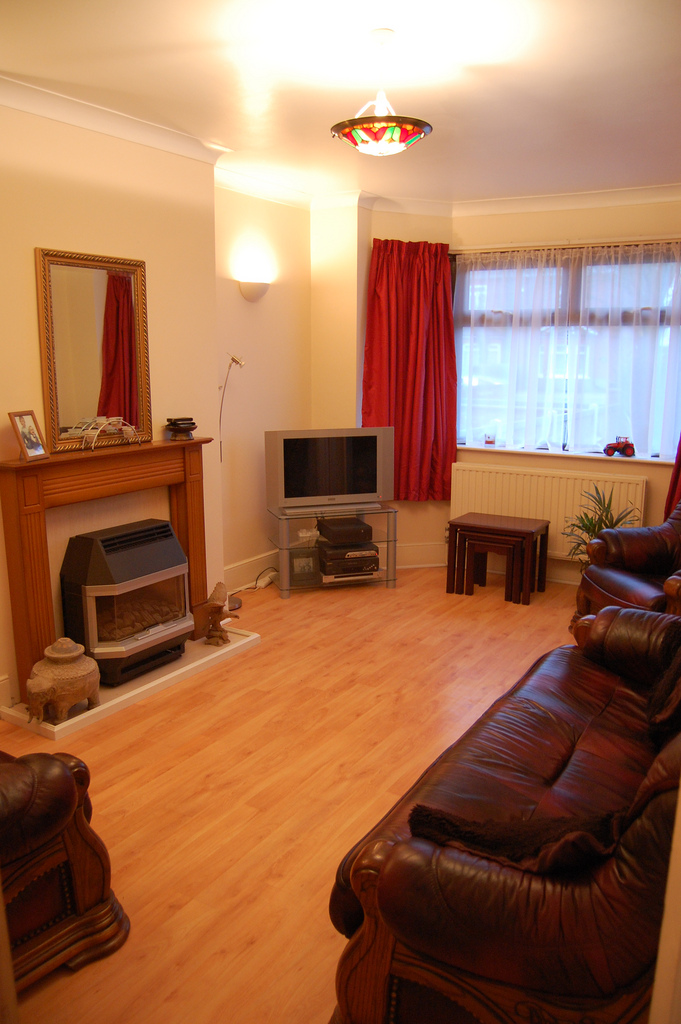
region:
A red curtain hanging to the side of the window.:
[369, 230, 452, 502]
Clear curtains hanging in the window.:
[458, 255, 676, 462]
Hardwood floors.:
[10, 556, 592, 1021]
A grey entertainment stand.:
[263, 508, 402, 596]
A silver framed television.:
[261, 430, 394, 509]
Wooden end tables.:
[440, 512, 545, 602]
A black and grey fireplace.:
[55, 527, 197, 679]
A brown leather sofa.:
[331, 610, 674, 1020]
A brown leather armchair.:
[576, 457, 679, 639]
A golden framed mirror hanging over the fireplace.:
[32, 249, 155, 449]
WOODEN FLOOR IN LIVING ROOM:
[30, 510, 676, 1013]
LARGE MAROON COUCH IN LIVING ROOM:
[407, 578, 638, 1019]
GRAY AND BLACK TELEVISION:
[246, 400, 415, 508]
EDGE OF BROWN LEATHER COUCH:
[4, 770, 127, 950]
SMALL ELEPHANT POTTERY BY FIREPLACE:
[17, 630, 117, 729]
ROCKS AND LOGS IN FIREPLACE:
[101, 577, 207, 638]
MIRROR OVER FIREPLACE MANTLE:
[44, 272, 136, 445]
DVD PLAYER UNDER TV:
[314, 530, 384, 584]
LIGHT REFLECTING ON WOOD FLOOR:
[400, 577, 496, 738]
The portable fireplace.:
[58, 522, 188, 677]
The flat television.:
[258, 422, 401, 510]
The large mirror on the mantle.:
[29, 242, 155, 457]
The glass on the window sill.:
[484, 424, 501, 450]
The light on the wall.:
[226, 227, 283, 320]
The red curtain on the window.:
[357, 229, 456, 523]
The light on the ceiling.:
[319, 29, 443, 164]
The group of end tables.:
[445, 501, 553, 615]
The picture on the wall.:
[7, 401, 46, 468]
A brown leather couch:
[315, 588, 675, 1015]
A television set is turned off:
[259, 418, 400, 526]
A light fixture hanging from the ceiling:
[322, 46, 434, 164]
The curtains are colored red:
[353, 227, 461, 507]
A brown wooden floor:
[1, 554, 584, 1017]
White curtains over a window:
[442, 229, 673, 466]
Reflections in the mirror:
[40, 256, 143, 434]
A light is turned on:
[217, 225, 286, 308]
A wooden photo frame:
[0, 403, 57, 466]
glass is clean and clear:
[50, 266, 141, 435]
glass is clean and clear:
[284, 433, 375, 499]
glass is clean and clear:
[578, 260, 678, 314]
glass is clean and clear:
[458, 326, 677, 462]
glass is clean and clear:
[93, 577, 185, 635]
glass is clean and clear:
[96, 519, 170, 557]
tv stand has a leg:
[383, 514, 397, 585]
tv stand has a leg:
[276, 518, 288, 593]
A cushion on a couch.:
[335, 767, 620, 933]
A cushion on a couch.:
[451, 705, 673, 836]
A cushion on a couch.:
[576, 605, 669, 684]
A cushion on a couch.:
[574, 561, 670, 638]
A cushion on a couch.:
[620, 532, 679, 578]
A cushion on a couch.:
[583, 527, 676, 569]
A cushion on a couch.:
[349, 835, 598, 990]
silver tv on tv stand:
[240, 422, 452, 630]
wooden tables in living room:
[421, 473, 573, 630]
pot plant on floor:
[549, 478, 647, 614]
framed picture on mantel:
[0, 395, 79, 493]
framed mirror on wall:
[21, 235, 182, 471]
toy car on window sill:
[582, 413, 666, 471]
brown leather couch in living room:
[320, 596, 677, 1020]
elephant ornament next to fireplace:
[12, 620, 145, 743]